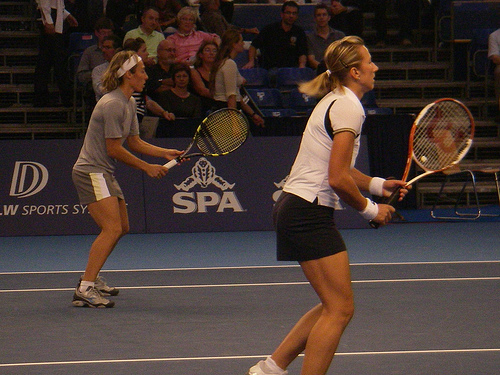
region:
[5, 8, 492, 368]
two women playing tennis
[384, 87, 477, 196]
a red and white tennis racket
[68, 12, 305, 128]
small crowd watching the tennis match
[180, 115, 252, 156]
yellow and black tennis racket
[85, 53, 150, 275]
woman wearing a gray outfit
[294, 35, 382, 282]
woman wearing a white shirt and black shorts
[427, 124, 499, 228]
an empty chair with silver legs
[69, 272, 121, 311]
gray and black athletic shoes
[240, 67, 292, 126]
blue seats in the bleachers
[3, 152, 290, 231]
blue and white advertisements lining the court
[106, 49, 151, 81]
White sweatband.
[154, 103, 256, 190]
Black and yellow tennis racket.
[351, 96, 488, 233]
Red and white tennis racket.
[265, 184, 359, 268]
Black sports shorts.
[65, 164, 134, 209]
Grey shorts.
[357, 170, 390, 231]
White wrist sweatbands.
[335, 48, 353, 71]
Black clip in hair.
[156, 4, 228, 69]
Woman in pink shirt.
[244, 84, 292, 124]
Blue seat.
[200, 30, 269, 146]
Woman walking.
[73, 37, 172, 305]
woman wearing white head band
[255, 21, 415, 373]
woman wearing white t-shirt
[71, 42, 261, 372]
woman holding black and yellow racket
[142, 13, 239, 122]
people sitting in the stands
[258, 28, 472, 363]
woman holding red and white racket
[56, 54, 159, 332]
woman wearing gray and black sneakers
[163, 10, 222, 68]
woman wearing pink shirt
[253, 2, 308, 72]
man wearing black shirt with logo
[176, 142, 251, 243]
sponsor of tennis game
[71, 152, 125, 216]
gray shorts with white stripe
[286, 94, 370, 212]
A WHITE TENNIS SHIRT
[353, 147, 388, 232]
A PAIR OF WHITE WRIST BANDS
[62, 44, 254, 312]
A WOMAN HOLDING A TENNIS RACKET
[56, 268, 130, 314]
A PAIR OF TENNIS SHOES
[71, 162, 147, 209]
A GRAY AND WHITE SKIRT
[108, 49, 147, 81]
A WHITE SWEATBAND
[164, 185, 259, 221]
THE WORD SPA IN WHITE LETTERS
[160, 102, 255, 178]
A YELLOW AND BLACK TENNIS RACKET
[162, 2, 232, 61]
A WOMAN WEARING A PINK SHIRT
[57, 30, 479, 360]
TWO WOMEN PLAYING TENNIS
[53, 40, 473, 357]
women playing tennic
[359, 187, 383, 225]
a whit band on the wrist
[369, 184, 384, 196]
a white band on the wrist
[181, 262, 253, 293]
white lines on the blue court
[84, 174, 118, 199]
thick white stripe on gray shorts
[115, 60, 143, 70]
white heaband around a head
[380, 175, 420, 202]
a hand holding a tennis racket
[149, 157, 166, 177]
a hand grasping a gray and yellow racket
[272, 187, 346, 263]
black shorts covering a bottom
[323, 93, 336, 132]
a black stripe on on a sleeve